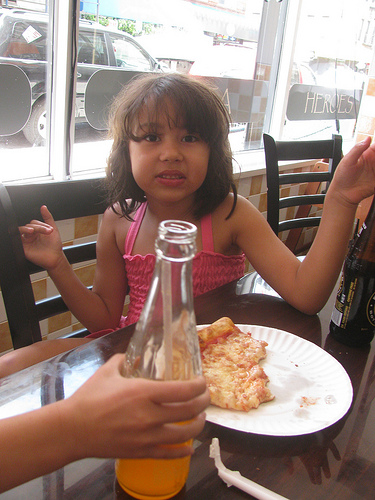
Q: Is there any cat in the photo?
A: No, there are no cats.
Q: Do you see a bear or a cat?
A: No, there are no cats or bears.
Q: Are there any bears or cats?
A: No, there are no cats or bears.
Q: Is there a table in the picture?
A: Yes, there is a table.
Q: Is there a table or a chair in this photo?
A: Yes, there is a table.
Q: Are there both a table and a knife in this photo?
A: No, there is a table but no knives.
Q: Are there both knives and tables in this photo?
A: No, there is a table but no knives.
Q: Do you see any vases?
A: No, there are no vases.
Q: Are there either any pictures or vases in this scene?
A: No, there are no vases or pictures.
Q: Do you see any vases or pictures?
A: No, there are no vases or pictures.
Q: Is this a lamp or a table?
A: This is a table.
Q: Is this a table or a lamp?
A: This is a table.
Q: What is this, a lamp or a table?
A: This is a table.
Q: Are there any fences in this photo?
A: No, there are no fences.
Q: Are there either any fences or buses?
A: No, there are no fences or buses.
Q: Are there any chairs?
A: Yes, there is a chair.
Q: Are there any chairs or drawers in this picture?
A: Yes, there is a chair.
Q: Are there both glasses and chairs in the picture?
A: No, there is a chair but no glasses.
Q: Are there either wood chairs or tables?
A: Yes, there is a wood chair.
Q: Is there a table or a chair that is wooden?
A: Yes, the chair is wooden.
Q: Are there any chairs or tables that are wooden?
A: Yes, the chair is wooden.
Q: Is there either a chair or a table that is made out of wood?
A: Yes, the chair is made of wood.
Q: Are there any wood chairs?
A: Yes, there is a wood chair.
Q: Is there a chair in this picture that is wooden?
A: Yes, there is a chair that is wooden.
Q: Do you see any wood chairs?
A: Yes, there is a chair that is made of wood.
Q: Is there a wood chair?
A: Yes, there is a chair that is made of wood.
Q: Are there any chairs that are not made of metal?
A: Yes, there is a chair that is made of wood.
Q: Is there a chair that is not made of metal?
A: Yes, there is a chair that is made of wood.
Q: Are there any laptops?
A: No, there are no laptops.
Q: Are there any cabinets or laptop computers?
A: No, there are no laptop computers or cabinets.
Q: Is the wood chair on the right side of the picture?
A: Yes, the chair is on the right of the image.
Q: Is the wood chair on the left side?
A: No, the chair is on the right of the image.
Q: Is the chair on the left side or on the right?
A: The chair is on the right of the image.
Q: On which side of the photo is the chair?
A: The chair is on the right of the image.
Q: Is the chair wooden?
A: Yes, the chair is wooden.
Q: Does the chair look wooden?
A: Yes, the chair is wooden.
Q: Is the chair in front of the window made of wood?
A: Yes, the chair is made of wood.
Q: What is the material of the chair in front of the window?
A: The chair is made of wood.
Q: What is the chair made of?
A: The chair is made of wood.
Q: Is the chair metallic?
A: No, the chair is wooden.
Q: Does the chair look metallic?
A: No, the chair is wooden.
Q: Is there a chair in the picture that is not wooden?
A: No, there is a chair but it is wooden.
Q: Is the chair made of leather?
A: No, the chair is made of wood.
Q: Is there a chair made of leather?
A: No, there is a chair but it is made of wood.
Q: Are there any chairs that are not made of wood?
A: No, there is a chair but it is made of wood.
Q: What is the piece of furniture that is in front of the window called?
A: The piece of furniture is a chair.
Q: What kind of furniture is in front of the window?
A: The piece of furniture is a chair.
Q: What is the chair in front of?
A: The chair is in front of the window.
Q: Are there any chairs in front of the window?
A: Yes, there is a chair in front of the window.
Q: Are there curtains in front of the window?
A: No, there is a chair in front of the window.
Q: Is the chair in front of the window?
A: Yes, the chair is in front of the window.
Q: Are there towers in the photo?
A: No, there are no towers.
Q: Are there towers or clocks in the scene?
A: No, there are no towers or clocks.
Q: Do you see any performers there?
A: No, there are no performers.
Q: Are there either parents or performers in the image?
A: No, there are no performers or parents.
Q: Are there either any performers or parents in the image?
A: No, there are no performers or parents.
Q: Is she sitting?
A: Yes, the girl is sitting.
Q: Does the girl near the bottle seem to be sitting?
A: Yes, the girl is sitting.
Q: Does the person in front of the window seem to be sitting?
A: Yes, the girl is sitting.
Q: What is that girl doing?
A: The girl is sitting.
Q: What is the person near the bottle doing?
A: The girl is sitting.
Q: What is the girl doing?
A: The girl is sitting.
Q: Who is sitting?
A: The girl is sitting.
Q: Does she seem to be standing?
A: No, the girl is sitting.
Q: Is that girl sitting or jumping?
A: The girl is sitting.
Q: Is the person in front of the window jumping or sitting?
A: The girl is sitting.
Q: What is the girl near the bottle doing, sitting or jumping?
A: The girl is sitting.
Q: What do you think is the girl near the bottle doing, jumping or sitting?
A: The girl is sitting.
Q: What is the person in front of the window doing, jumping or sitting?
A: The girl is sitting.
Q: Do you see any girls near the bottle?
A: Yes, there is a girl near the bottle.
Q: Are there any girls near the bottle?
A: Yes, there is a girl near the bottle.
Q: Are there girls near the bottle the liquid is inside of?
A: Yes, there is a girl near the bottle.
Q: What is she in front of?
A: The girl is in front of the window.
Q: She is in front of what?
A: The girl is in front of the window.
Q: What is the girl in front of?
A: The girl is in front of the window.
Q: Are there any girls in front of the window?
A: Yes, there is a girl in front of the window.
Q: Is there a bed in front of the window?
A: No, there is a girl in front of the window.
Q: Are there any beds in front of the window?
A: No, there is a girl in front of the window.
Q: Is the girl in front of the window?
A: Yes, the girl is in front of the window.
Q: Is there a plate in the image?
A: Yes, there is a plate.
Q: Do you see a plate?
A: Yes, there is a plate.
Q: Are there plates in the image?
A: Yes, there is a plate.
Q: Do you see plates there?
A: Yes, there is a plate.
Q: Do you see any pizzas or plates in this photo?
A: Yes, there is a plate.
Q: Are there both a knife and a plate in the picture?
A: No, there is a plate but no knives.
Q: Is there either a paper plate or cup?
A: Yes, there is a paper plate.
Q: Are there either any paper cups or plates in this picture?
A: Yes, there is a paper plate.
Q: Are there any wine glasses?
A: No, there are no wine glasses.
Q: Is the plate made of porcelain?
A: No, the plate is made of paper.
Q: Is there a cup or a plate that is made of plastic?
A: No, there is a plate but it is made of paper.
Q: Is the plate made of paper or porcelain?
A: The plate is made of paper.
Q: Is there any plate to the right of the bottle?
A: Yes, there is a plate to the right of the bottle.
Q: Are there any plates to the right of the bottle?
A: Yes, there is a plate to the right of the bottle.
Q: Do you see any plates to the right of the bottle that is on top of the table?
A: Yes, there is a plate to the right of the bottle.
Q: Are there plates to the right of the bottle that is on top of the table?
A: Yes, there is a plate to the right of the bottle.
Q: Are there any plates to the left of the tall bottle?
A: No, the plate is to the right of the bottle.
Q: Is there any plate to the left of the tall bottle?
A: No, the plate is to the right of the bottle.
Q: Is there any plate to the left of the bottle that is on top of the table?
A: No, the plate is to the right of the bottle.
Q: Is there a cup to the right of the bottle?
A: No, there is a plate to the right of the bottle.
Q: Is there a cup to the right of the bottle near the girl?
A: No, there is a plate to the right of the bottle.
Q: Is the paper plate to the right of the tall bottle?
A: Yes, the plate is to the right of the bottle.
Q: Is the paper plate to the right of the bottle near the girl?
A: Yes, the plate is to the right of the bottle.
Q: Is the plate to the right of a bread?
A: No, the plate is to the right of the bottle.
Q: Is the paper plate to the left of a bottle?
A: No, the plate is to the right of a bottle.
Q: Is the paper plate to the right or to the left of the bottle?
A: The plate is to the right of the bottle.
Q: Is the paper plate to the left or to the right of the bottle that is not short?
A: The plate is to the right of the bottle.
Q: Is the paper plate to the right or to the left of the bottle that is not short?
A: The plate is to the right of the bottle.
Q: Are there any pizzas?
A: Yes, there is a pizza.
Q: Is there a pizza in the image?
A: Yes, there is a pizza.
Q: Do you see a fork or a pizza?
A: Yes, there is a pizza.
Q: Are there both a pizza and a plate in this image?
A: Yes, there are both a pizza and a plate.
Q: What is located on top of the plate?
A: The pizza is on top of the plate.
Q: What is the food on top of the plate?
A: The food is a pizza.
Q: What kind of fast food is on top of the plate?
A: The food is a pizza.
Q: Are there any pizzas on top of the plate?
A: Yes, there is a pizza on top of the plate.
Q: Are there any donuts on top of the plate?
A: No, there is a pizza on top of the plate.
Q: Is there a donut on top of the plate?
A: No, there is a pizza on top of the plate.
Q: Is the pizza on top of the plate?
A: Yes, the pizza is on top of the plate.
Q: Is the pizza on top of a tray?
A: No, the pizza is on top of the plate.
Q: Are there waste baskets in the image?
A: No, there are no waste baskets.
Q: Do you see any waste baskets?
A: No, there are no waste baskets.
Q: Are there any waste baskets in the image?
A: No, there are no waste baskets.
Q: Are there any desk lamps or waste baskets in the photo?
A: No, there are no waste baskets or desk lamps.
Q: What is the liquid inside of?
A: The liquid is inside the bottle.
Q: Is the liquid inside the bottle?
A: Yes, the liquid is inside the bottle.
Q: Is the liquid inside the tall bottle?
A: Yes, the liquid is inside the bottle.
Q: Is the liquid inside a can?
A: No, the liquid is inside the bottle.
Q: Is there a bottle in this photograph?
A: Yes, there is a bottle.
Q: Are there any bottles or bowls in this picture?
A: Yes, there is a bottle.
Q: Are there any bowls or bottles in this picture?
A: Yes, there is a bottle.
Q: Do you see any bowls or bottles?
A: Yes, there is a bottle.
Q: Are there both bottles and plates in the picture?
A: Yes, there are both a bottle and a plate.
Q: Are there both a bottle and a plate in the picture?
A: Yes, there are both a bottle and a plate.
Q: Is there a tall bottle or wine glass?
A: Yes, there is a tall bottle.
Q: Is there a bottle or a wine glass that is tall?
A: Yes, the bottle is tall.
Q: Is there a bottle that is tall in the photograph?
A: Yes, there is a tall bottle.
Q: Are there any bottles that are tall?
A: Yes, there is a bottle that is tall.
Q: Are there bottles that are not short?
A: Yes, there is a tall bottle.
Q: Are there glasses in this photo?
A: No, there are no glasses.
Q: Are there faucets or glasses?
A: No, there are no glasses or faucets.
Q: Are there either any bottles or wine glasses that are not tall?
A: No, there is a bottle but it is tall.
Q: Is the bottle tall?
A: Yes, the bottle is tall.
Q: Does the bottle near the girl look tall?
A: Yes, the bottle is tall.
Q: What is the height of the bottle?
A: The bottle is tall.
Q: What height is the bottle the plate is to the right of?
A: The bottle is tall.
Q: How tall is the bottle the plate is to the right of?
A: The bottle is tall.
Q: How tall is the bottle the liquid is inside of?
A: The bottle is tall.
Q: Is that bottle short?
A: No, the bottle is tall.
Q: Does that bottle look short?
A: No, the bottle is tall.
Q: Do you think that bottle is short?
A: No, the bottle is tall.